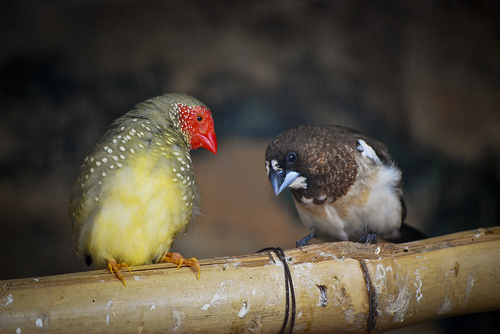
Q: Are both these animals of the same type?
A: Yes, all the animals are birds.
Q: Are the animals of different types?
A: No, all the animals are birds.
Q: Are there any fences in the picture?
A: No, there are no fences.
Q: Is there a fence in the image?
A: No, there are no fences.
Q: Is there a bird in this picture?
A: Yes, there is a bird.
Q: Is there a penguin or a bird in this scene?
A: Yes, there is a bird.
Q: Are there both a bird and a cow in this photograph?
A: No, there is a bird but no cows.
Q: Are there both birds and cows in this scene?
A: No, there is a bird but no cows.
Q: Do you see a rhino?
A: No, there are no rhinos.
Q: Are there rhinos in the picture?
A: No, there are no rhinos.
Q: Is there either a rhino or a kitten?
A: No, there are no rhinos or kittens.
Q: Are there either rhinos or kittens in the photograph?
A: No, there are no rhinos or kittens.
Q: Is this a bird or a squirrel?
A: This is a bird.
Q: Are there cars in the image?
A: No, there are no cars.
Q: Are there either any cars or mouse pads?
A: No, there are no cars or mouse pads.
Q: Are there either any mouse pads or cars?
A: No, there are no cars or mouse pads.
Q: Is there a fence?
A: No, there are no fences.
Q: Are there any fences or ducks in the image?
A: No, there are no fences or ducks.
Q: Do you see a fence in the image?
A: No, there are no fences.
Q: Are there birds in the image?
A: Yes, there is a bird.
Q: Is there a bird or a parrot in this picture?
A: Yes, there is a bird.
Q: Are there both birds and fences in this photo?
A: No, there is a bird but no fences.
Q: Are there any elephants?
A: No, there are no elephants.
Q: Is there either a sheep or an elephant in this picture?
A: No, there are no elephants or sheep.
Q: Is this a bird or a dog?
A: This is a bird.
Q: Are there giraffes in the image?
A: No, there are no giraffes.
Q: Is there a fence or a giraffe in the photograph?
A: No, there are no giraffes or fences.